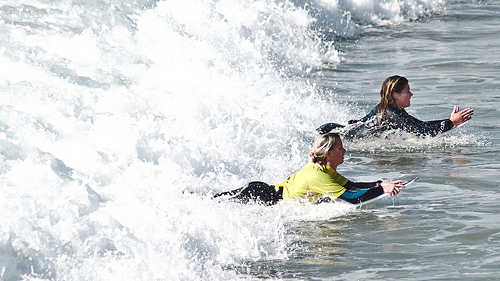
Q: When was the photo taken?
A: Daytime.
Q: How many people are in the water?
A: Two.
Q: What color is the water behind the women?
A: White.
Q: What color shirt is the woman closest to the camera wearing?
A: Yellow.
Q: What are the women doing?
A: Surfing.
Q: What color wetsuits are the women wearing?
A: Black.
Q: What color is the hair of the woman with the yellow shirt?
A: Blonde.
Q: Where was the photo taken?
A: On a beach.